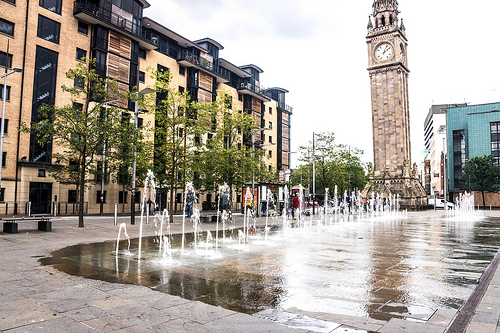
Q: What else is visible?
A: Water.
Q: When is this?
A: Daytime.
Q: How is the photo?
A: Clear.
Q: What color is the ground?
A: Gray.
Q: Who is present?
A: No one.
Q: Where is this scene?
A: At a fountain.